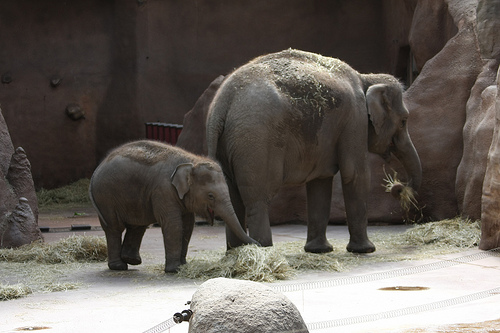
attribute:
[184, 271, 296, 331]
rock — rounded, grey, small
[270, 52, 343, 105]
grass — piled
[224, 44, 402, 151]
elephant — large, eating, small, larger, gray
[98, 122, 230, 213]
baby — next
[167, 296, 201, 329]
spring — attached, black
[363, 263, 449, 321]
mud — piled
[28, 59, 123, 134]
objects — poking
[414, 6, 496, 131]
rocks — towered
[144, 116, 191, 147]
bars — behind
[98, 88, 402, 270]
elephants — gray, eating, baby, enclosed, near rocks, facing, picking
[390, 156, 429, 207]
hay — eaten, piled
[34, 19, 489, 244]
exhibit — rocky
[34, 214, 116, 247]
ropes — white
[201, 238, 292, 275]
food — plied, scattered